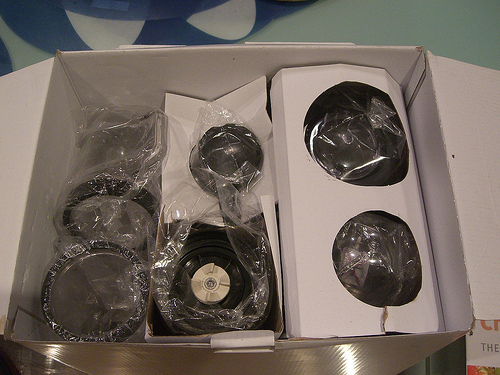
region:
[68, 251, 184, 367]
Plastic around container.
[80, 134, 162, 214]
Plastic around clear blender.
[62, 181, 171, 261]
Black ring on bottom of blender.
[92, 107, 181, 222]
Blender is clear in color.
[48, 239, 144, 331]
Black ring around blender.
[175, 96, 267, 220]
White cardboard around blender piece.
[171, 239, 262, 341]
Black ring around bottom of blender.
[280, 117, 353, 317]
White cardboard around blender pieces.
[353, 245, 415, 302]
Clear plastic wrap around blender pieces.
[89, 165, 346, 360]
Blender pieces in large white box.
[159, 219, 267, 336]
a small object inside box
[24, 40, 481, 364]
a box containing speakers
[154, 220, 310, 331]
a small speaker in box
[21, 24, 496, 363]
a big box with speakers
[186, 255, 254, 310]
a small part in middle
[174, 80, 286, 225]
a white paper of box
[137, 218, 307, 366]
a white cover on speaker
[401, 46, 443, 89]
the box fold joint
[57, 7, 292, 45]
two white marks outside the box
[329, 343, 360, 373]
white light shining in box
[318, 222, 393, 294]
part of a polythene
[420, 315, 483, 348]
edge of a box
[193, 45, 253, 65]
edge of a box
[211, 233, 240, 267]
edge of a wheel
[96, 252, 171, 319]
part of a polythene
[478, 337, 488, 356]
part of a letter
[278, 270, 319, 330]
part of a carton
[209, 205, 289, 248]
plastic wrapping over item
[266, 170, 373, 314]
white protective cardboard in box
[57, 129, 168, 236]
plastic wrap over items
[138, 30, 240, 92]
outer edge of white box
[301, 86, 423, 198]
circular opening for item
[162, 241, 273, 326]
black bottom of item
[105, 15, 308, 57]
blue floor in back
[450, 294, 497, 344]
corner of white box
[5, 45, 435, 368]
box holding multiple items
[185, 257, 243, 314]
center of bottom of item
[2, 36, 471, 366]
box with plastic parts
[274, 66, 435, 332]
cardboard with circular cutouts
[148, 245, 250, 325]
bottom of blender with blade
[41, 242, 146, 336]
cup for nutri bullet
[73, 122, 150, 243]
cup for nutri bullet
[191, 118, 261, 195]
part of nutri bullet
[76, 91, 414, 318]
contents of open box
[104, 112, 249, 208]
plastic wrap around items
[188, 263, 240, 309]
white knob on bottom of item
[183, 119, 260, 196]
plastic part of bullet